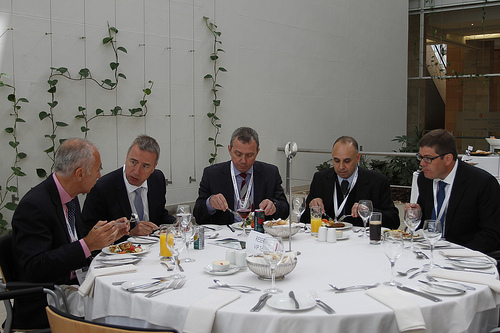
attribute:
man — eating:
[12, 133, 133, 332]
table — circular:
[76, 216, 500, 332]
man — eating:
[79, 133, 181, 250]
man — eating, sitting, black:
[194, 123, 293, 226]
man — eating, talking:
[301, 135, 402, 231]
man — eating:
[404, 127, 499, 258]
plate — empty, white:
[270, 287, 319, 314]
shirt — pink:
[50, 172, 94, 280]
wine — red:
[234, 207, 252, 219]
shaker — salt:
[316, 224, 328, 244]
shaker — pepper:
[327, 224, 339, 242]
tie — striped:
[238, 171, 250, 207]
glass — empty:
[424, 215, 446, 271]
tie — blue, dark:
[433, 180, 447, 230]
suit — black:
[11, 171, 97, 332]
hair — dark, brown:
[415, 126, 458, 160]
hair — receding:
[52, 133, 99, 179]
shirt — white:
[120, 164, 156, 226]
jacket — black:
[298, 160, 402, 230]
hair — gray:
[126, 134, 163, 166]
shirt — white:
[420, 156, 458, 234]